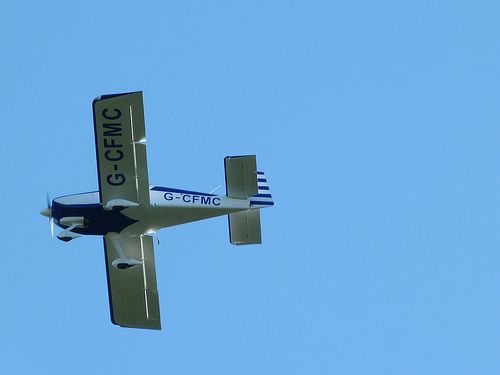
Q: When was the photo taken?
A: Daytime.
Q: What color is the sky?
A: Blue.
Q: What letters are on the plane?
A: G-CFMC.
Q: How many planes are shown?
A: One.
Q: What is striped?
A: Tail of plane.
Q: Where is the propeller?
A: Front of plane.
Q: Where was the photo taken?
A: In the air.